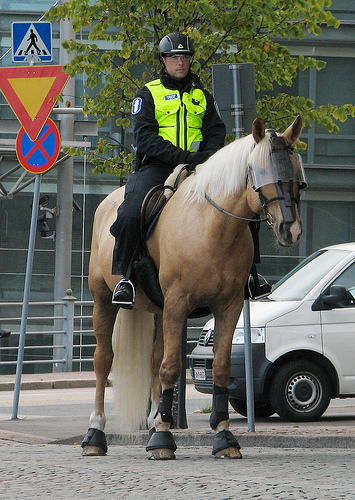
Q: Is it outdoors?
A: Yes, it is outdoors.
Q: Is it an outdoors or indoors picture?
A: It is outdoors.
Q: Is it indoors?
A: No, it is outdoors.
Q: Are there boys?
A: No, there are no boys.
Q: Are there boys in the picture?
A: No, there are no boys.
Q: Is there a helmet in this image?
A: Yes, there is a helmet.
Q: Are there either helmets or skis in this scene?
A: Yes, there is a helmet.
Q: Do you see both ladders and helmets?
A: No, there is a helmet but no ladders.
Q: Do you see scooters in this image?
A: No, there are no scooters.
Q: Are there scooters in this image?
A: No, there are no scooters.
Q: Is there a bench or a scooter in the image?
A: No, there are no scooters or benches.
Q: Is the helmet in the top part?
A: Yes, the helmet is in the top of the image.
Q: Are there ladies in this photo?
A: No, there are no ladies.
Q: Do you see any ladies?
A: No, there are no ladies.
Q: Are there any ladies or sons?
A: No, there are no ladies or sons.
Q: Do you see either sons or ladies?
A: No, there are no ladies or sons.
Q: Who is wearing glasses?
A: The man is wearing glasses.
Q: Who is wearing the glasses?
A: The man is wearing glasses.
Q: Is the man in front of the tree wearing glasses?
A: Yes, the man is wearing glasses.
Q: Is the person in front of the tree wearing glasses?
A: Yes, the man is wearing glasses.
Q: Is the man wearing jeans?
A: No, the man is wearing glasses.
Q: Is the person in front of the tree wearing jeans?
A: No, the man is wearing glasses.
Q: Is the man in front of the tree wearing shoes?
A: Yes, the man is wearing shoes.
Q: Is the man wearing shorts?
A: No, the man is wearing shoes.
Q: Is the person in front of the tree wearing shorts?
A: No, the man is wearing shoes.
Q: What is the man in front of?
A: The man is in front of the tree.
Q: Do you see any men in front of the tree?
A: Yes, there is a man in front of the tree.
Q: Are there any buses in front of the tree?
A: No, there is a man in front of the tree.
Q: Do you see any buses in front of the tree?
A: No, there is a man in front of the tree.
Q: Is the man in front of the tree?
A: Yes, the man is in front of the tree.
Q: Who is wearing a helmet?
A: The man is wearing a helmet.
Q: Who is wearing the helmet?
A: The man is wearing a helmet.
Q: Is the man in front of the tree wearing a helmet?
A: Yes, the man is wearing a helmet.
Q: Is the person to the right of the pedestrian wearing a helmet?
A: Yes, the man is wearing a helmet.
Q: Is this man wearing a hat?
A: No, the man is wearing a helmet.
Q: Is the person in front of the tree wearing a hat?
A: No, the man is wearing a helmet.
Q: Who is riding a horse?
A: The man is riding a horse.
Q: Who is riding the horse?
A: The man is riding a horse.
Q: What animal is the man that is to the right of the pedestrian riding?
A: The man is riding a horse.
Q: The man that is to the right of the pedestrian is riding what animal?
A: The man is riding a horse.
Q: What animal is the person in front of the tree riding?
A: The man is riding a horse.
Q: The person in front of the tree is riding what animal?
A: The man is riding a horse.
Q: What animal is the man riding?
A: The man is riding a horse.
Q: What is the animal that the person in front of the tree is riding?
A: The animal is a horse.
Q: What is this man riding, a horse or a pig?
A: The man is riding a horse.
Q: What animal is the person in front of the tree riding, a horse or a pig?
A: The man is riding a horse.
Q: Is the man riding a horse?
A: Yes, the man is riding a horse.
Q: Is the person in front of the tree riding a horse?
A: Yes, the man is riding a horse.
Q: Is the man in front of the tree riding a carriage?
A: No, the man is riding a horse.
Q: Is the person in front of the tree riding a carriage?
A: No, the man is riding a horse.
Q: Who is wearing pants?
A: The man is wearing pants.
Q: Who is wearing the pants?
A: The man is wearing pants.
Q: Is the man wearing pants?
A: Yes, the man is wearing pants.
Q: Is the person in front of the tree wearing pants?
A: Yes, the man is wearing pants.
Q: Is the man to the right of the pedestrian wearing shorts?
A: No, the man is wearing pants.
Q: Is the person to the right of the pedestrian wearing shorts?
A: No, the man is wearing pants.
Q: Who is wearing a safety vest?
A: The man is wearing a safety vest.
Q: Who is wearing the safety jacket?
A: The man is wearing a safety vest.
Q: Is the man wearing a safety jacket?
A: Yes, the man is wearing a safety jacket.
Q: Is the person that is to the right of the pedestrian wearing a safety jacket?
A: Yes, the man is wearing a safety jacket.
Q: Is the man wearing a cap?
A: No, the man is wearing a safety jacket.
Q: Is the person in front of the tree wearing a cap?
A: No, the man is wearing a safety jacket.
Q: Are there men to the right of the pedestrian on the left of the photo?
A: Yes, there is a man to the right of the pedestrian.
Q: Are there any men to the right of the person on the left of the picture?
A: Yes, there is a man to the right of the pedestrian.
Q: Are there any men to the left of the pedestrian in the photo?
A: No, the man is to the right of the pedestrian.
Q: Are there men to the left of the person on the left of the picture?
A: No, the man is to the right of the pedestrian.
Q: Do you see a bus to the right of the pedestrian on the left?
A: No, there is a man to the right of the pedestrian.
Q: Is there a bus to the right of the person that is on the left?
A: No, there is a man to the right of the pedestrian.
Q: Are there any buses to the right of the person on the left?
A: No, there is a man to the right of the pedestrian.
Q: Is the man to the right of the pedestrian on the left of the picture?
A: Yes, the man is to the right of the pedestrian.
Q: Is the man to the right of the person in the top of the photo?
A: Yes, the man is to the right of the pedestrian.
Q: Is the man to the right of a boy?
A: No, the man is to the right of the pedestrian.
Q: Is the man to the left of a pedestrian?
A: No, the man is to the right of a pedestrian.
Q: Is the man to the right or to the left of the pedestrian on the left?
A: The man is to the right of the pedestrian.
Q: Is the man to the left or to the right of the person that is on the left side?
A: The man is to the right of the pedestrian.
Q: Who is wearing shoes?
A: The man is wearing shoes.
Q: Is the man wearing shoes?
A: Yes, the man is wearing shoes.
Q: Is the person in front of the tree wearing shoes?
A: Yes, the man is wearing shoes.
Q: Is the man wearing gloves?
A: No, the man is wearing shoes.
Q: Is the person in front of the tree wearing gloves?
A: No, the man is wearing shoes.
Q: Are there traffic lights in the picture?
A: No, there are no traffic lights.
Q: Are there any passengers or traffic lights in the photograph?
A: No, there are no traffic lights or passengers.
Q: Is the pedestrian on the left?
A: Yes, the pedestrian is on the left of the image.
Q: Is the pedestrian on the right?
A: No, the pedestrian is on the left of the image.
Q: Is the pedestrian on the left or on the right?
A: The pedestrian is on the left of the image.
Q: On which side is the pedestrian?
A: The pedestrian is on the left of the image.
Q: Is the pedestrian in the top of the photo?
A: Yes, the pedestrian is in the top of the image.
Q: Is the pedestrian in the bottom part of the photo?
A: No, the pedestrian is in the top of the image.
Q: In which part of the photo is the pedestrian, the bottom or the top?
A: The pedestrian is in the top of the image.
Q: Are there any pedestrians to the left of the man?
A: Yes, there is a pedestrian to the left of the man.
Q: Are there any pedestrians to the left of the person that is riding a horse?
A: Yes, there is a pedestrian to the left of the man.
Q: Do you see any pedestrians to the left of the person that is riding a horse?
A: Yes, there is a pedestrian to the left of the man.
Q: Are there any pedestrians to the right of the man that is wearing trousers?
A: No, the pedestrian is to the left of the man.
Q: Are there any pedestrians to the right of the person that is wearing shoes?
A: No, the pedestrian is to the left of the man.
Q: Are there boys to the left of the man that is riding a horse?
A: No, there is a pedestrian to the left of the man.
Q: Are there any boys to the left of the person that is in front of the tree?
A: No, there is a pedestrian to the left of the man.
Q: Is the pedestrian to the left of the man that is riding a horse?
A: Yes, the pedestrian is to the left of the man.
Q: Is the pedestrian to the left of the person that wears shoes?
A: Yes, the pedestrian is to the left of the man.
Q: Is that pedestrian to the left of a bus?
A: No, the pedestrian is to the left of the man.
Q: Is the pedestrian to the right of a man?
A: No, the pedestrian is to the left of a man.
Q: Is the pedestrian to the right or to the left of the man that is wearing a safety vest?
A: The pedestrian is to the left of the man.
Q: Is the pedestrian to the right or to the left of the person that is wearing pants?
A: The pedestrian is to the left of the man.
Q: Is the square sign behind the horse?
A: Yes, the sign is behind the horse.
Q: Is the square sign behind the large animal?
A: Yes, the sign is behind the horse.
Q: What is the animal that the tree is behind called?
A: The animal is a horse.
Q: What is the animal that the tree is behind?
A: The animal is a horse.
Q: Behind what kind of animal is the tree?
A: The tree is behind the horse.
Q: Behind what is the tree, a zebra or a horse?
A: The tree is behind a horse.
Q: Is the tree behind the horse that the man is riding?
A: Yes, the tree is behind the horse.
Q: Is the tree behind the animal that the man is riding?
A: Yes, the tree is behind the horse.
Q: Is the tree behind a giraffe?
A: No, the tree is behind the horse.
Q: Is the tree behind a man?
A: Yes, the tree is behind a man.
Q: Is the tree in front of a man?
A: No, the tree is behind a man.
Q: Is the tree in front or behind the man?
A: The tree is behind the man.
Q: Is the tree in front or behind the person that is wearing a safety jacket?
A: The tree is behind the man.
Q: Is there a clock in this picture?
A: No, there are no clocks.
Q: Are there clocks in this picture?
A: No, there are no clocks.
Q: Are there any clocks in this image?
A: No, there are no clocks.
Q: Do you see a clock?
A: No, there are no clocks.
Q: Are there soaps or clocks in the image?
A: No, there are no clocks or soaps.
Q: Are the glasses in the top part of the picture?
A: Yes, the glasses are in the top of the image.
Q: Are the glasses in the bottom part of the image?
A: No, the glasses are in the top of the image.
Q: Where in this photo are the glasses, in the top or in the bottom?
A: The glasses are in the top of the image.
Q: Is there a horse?
A: Yes, there is a horse.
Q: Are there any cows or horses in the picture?
A: Yes, there is a horse.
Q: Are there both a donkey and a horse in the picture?
A: No, there is a horse but no donkeys.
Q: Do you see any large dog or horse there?
A: Yes, there is a large horse.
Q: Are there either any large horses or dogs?
A: Yes, there is a large horse.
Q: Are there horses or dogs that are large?
A: Yes, the horse is large.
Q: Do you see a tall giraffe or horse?
A: Yes, there is a tall horse.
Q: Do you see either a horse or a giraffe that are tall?
A: Yes, the horse is tall.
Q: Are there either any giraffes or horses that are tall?
A: Yes, the horse is tall.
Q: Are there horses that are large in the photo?
A: Yes, there is a large horse.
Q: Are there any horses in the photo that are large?
A: Yes, there is a horse that is large.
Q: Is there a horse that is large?
A: Yes, there is a horse that is large.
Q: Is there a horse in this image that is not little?
A: Yes, there is a large horse.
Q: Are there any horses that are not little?
A: Yes, there is a large horse.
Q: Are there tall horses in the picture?
A: Yes, there is a tall horse.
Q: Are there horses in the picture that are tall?
A: Yes, there is a horse that is tall.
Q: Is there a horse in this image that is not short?
A: Yes, there is a tall horse.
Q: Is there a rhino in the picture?
A: No, there are no rhinos.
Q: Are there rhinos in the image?
A: No, there are no rhinos.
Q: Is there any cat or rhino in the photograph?
A: No, there are no rhinos or cats.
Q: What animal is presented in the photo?
A: The animal is a horse.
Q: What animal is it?
A: The animal is a horse.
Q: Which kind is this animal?
A: That is a horse.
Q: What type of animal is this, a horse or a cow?
A: That is a horse.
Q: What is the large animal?
A: The animal is a horse.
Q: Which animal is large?
A: The animal is a horse.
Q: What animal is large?
A: The animal is a horse.